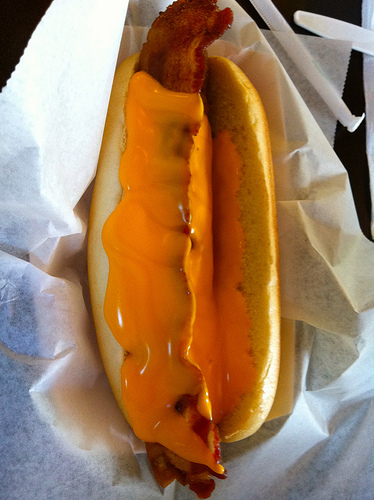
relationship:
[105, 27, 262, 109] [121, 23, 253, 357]
top of bacon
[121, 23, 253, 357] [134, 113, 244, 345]
bacon strip with cheese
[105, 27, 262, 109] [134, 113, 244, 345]
edge of bacon strip with cheese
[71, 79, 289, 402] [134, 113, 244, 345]
hotdog bun in cheese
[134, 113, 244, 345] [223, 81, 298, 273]
cheese dripping bun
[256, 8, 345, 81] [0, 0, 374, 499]
straw on black table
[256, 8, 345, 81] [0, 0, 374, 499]
plastic knife on black table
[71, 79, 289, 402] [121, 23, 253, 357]
hotdog with bacon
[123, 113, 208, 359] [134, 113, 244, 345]
bright yellow cheese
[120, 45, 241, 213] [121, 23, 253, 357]
strips of bacon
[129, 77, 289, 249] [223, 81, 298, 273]
toasty yellow bun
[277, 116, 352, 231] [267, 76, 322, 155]
white wax paper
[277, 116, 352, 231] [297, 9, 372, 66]
white plastic handle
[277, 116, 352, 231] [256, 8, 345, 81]
white paper straw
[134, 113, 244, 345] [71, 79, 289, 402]
cheese covered hotdog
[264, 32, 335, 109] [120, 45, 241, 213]
black table with food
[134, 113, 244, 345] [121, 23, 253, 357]
cheese and bacon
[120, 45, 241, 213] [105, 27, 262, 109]
orange cheese top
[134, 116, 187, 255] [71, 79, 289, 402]
orange cheese on hotdog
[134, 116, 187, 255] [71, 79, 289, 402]
orange cheese top on hotdog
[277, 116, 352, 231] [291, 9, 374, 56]
white plastic handle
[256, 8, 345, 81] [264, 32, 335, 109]
straw in wrapper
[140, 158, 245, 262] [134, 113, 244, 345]
melted yellow cheese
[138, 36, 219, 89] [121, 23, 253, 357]
end of bacon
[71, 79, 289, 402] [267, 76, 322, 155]
hotdog bun on paper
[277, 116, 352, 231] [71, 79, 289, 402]
white paper under hotdog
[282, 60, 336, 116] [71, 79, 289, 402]
black table under hotdog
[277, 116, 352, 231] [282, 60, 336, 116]
white napkin on black table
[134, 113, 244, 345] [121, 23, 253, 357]
cheese on bacon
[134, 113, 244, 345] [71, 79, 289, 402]
cheese on hotdog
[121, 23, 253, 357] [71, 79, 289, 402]
bacon on hotdog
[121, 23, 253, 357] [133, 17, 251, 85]
bacon sticking out other end